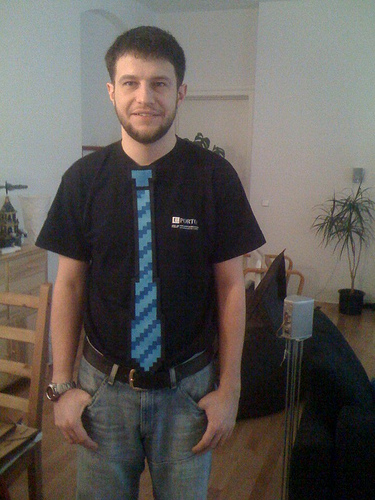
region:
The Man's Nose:
[135, 87, 154, 110]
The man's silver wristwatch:
[38, 373, 78, 403]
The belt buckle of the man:
[126, 369, 169, 393]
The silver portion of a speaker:
[274, 287, 319, 346]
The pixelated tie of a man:
[125, 166, 169, 373]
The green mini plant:
[303, 179, 373, 318]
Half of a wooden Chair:
[1, 283, 47, 421]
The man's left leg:
[151, 377, 210, 499]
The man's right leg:
[79, 396, 143, 498]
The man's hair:
[99, 24, 190, 58]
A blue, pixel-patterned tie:
[124, 167, 168, 382]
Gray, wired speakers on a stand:
[267, 290, 316, 498]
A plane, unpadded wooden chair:
[1, 271, 56, 499]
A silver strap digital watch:
[40, 377, 81, 403]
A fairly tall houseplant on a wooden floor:
[305, 168, 373, 316]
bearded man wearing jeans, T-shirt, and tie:
[32, 22, 274, 499]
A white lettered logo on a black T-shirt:
[165, 210, 204, 233]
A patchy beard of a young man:
[102, 79, 181, 144]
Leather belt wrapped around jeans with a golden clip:
[70, 332, 221, 395]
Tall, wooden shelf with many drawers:
[0, 175, 56, 397]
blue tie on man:
[128, 163, 169, 359]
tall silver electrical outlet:
[282, 289, 312, 426]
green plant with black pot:
[340, 193, 367, 315]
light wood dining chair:
[7, 276, 52, 471]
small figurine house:
[0, 190, 27, 261]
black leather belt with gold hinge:
[100, 344, 205, 416]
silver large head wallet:
[40, 381, 85, 419]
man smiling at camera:
[66, 12, 211, 308]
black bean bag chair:
[256, 278, 354, 426]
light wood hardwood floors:
[241, 441, 263, 493]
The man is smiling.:
[94, 16, 195, 151]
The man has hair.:
[96, 18, 194, 156]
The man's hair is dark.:
[97, 18, 200, 155]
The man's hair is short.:
[97, 18, 195, 159]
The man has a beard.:
[94, 20, 196, 163]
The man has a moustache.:
[100, 23, 199, 147]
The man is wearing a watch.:
[30, 16, 280, 456]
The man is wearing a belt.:
[31, 21, 254, 459]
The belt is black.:
[71, 332, 219, 407]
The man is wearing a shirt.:
[28, 23, 271, 377]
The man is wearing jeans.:
[34, 19, 264, 499]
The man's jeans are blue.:
[30, 24, 268, 498]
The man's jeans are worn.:
[35, 21, 273, 499]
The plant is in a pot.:
[303, 176, 374, 324]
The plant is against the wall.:
[248, 1, 373, 320]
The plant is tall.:
[261, 3, 374, 323]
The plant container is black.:
[312, 176, 372, 321]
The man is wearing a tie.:
[36, 16, 267, 384]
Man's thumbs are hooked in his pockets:
[31, 17, 284, 458]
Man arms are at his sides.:
[32, 20, 266, 459]